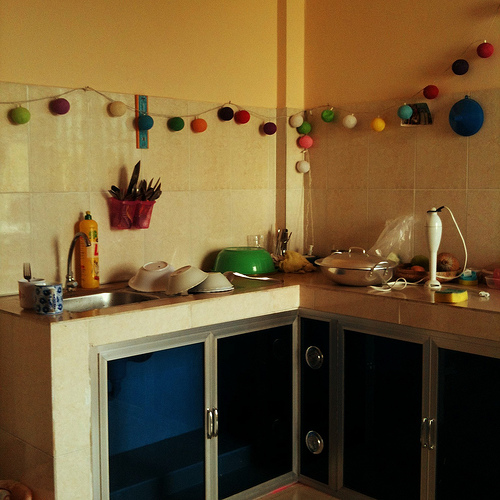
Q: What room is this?
A: It is a kitchen.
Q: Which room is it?
A: It is a kitchen.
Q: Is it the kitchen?
A: Yes, it is the kitchen.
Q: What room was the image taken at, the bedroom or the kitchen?
A: It was taken at the kitchen.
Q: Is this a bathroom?
A: No, it is a kitchen.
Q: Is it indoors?
A: Yes, it is indoors.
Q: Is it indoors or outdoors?
A: It is indoors.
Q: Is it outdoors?
A: No, it is indoors.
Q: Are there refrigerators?
A: No, there are no refrigerators.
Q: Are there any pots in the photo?
A: Yes, there is a pot.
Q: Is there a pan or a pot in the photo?
A: Yes, there is a pot.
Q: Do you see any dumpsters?
A: No, there are no dumpsters.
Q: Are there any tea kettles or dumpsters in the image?
A: No, there are no dumpsters or tea kettles.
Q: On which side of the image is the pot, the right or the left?
A: The pot is on the right of the image.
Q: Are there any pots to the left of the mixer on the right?
A: Yes, there is a pot to the left of the mixer.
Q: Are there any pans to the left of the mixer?
A: No, there is a pot to the left of the mixer.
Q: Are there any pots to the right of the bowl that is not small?
A: Yes, there is a pot to the right of the bowl.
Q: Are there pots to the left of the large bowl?
A: No, the pot is to the right of the bowl.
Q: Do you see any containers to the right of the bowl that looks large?
A: No, there is a pot to the right of the bowl.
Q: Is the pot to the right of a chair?
A: No, the pot is to the right of the bowl.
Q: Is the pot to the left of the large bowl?
A: No, the pot is to the right of the bowl.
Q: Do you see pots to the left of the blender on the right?
A: Yes, there is a pot to the left of the blender.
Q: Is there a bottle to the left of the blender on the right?
A: No, there is a pot to the left of the blender.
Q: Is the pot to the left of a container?
A: No, the pot is to the left of the blender.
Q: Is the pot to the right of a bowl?
A: Yes, the pot is to the right of a bowl.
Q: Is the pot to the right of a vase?
A: No, the pot is to the right of a bowl.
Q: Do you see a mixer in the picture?
A: Yes, there is a mixer.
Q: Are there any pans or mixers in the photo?
A: Yes, there is a mixer.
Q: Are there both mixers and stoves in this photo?
A: No, there is a mixer but no stoves.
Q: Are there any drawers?
A: No, there are no drawers.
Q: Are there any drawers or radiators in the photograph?
A: No, there are no drawers or radiators.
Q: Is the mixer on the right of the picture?
A: Yes, the mixer is on the right of the image.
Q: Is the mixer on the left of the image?
A: No, the mixer is on the right of the image.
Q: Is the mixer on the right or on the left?
A: The mixer is on the right of the image.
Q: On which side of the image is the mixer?
A: The mixer is on the right of the image.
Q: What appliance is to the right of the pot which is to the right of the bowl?
A: The appliance is a mixer.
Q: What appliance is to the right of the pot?
A: The appliance is a mixer.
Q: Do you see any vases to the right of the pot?
A: No, there is a mixer to the right of the pot.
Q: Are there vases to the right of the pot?
A: No, there is a mixer to the right of the pot.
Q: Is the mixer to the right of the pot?
A: Yes, the mixer is to the right of the pot.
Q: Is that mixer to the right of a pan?
A: No, the mixer is to the right of the pot.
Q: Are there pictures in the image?
A: No, there are no pictures.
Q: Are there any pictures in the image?
A: No, there are no pictures.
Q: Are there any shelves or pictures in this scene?
A: No, there are no pictures or shelves.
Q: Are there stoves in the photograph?
A: No, there are no stoves.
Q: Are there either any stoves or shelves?
A: No, there are no stoves or shelves.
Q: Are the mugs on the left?
A: Yes, the mugs are on the left of the image.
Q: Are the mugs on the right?
A: No, the mugs are on the left of the image.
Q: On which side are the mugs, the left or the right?
A: The mugs are on the left of the image.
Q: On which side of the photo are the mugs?
A: The mugs are on the left of the image.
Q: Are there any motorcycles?
A: No, there are no motorcycles.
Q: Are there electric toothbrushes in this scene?
A: No, there are no electric toothbrushes.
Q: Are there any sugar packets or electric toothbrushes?
A: No, there are no electric toothbrushes or sugar packets.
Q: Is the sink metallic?
A: Yes, the sink is metallic.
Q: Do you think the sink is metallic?
A: Yes, the sink is metallic.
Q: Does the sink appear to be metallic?
A: Yes, the sink is metallic.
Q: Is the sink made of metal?
A: Yes, the sink is made of metal.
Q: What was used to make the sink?
A: The sink is made of metal.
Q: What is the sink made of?
A: The sink is made of metal.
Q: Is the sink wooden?
A: No, the sink is metallic.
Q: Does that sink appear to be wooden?
A: No, the sink is metallic.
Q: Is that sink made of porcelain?
A: No, the sink is made of metal.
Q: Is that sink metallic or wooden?
A: The sink is metallic.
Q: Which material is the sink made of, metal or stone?
A: The sink is made of metal.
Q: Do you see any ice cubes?
A: No, there are no ice cubes.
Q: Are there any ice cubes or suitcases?
A: No, there are no ice cubes or suitcases.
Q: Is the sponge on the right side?
A: Yes, the sponge is on the right of the image.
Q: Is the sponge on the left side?
A: No, the sponge is on the right of the image.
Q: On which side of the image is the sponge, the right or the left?
A: The sponge is on the right of the image.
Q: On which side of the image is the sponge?
A: The sponge is on the right of the image.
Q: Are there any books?
A: No, there are no books.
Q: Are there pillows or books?
A: No, there are no books or pillows.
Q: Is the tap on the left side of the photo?
A: Yes, the tap is on the left of the image.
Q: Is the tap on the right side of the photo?
A: No, the tap is on the left of the image.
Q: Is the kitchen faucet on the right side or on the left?
A: The faucet is on the left of the image.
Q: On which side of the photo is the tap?
A: The tap is on the left of the image.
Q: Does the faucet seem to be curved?
A: Yes, the faucet is curved.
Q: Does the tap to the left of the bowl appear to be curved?
A: Yes, the faucet is curved.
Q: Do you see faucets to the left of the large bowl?
A: Yes, there is a faucet to the left of the bowl.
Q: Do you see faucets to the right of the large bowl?
A: No, the faucet is to the left of the bowl.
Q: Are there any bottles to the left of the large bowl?
A: No, there is a faucet to the left of the bowl.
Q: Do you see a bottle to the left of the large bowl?
A: No, there is a faucet to the left of the bowl.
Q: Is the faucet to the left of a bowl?
A: Yes, the faucet is to the left of a bowl.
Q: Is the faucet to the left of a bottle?
A: No, the faucet is to the left of a bowl.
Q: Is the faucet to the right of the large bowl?
A: No, the faucet is to the left of the bowl.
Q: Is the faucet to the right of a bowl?
A: No, the faucet is to the left of a bowl.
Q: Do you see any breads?
A: No, there are no breads.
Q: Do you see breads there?
A: No, there are no breads.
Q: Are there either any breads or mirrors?
A: No, there are no breads or mirrors.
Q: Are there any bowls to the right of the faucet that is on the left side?
A: Yes, there is a bowl to the right of the faucet.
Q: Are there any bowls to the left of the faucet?
A: No, the bowl is to the right of the faucet.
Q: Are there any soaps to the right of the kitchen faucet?
A: No, there is a bowl to the right of the faucet.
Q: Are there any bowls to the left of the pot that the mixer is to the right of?
A: Yes, there is a bowl to the left of the pot.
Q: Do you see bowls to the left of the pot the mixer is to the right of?
A: Yes, there is a bowl to the left of the pot.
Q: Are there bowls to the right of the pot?
A: No, the bowl is to the left of the pot.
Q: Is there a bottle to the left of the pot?
A: No, there is a bowl to the left of the pot.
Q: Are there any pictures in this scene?
A: No, there are no pictures.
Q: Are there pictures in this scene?
A: No, there are no pictures.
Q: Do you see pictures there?
A: No, there are no pictures.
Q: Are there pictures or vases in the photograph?
A: No, there are no pictures or vases.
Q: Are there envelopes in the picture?
A: No, there are no envelopes.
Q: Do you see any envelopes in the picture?
A: No, there are no envelopes.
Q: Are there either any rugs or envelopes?
A: No, there are no envelopes or rugs.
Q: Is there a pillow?
A: No, there are no pillows.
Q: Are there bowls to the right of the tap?
A: Yes, there is a bowl to the right of the tap.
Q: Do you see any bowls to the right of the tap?
A: Yes, there is a bowl to the right of the tap.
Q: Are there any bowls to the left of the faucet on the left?
A: No, the bowl is to the right of the faucet.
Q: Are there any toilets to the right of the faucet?
A: No, there is a bowl to the right of the faucet.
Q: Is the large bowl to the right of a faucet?
A: Yes, the bowl is to the right of a faucet.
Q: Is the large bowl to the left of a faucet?
A: No, the bowl is to the right of a faucet.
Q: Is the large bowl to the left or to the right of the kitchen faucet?
A: The bowl is to the right of the tap.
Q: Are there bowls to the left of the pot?
A: Yes, there is a bowl to the left of the pot.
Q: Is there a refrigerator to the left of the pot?
A: No, there is a bowl to the left of the pot.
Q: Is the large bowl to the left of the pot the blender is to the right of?
A: Yes, the bowl is to the left of the pot.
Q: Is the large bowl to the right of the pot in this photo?
A: No, the bowl is to the left of the pot.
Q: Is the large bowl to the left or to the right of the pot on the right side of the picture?
A: The bowl is to the left of the pot.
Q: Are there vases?
A: No, there are no vases.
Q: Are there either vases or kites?
A: No, there are no vases or kites.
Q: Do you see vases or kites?
A: No, there are no vases or kites.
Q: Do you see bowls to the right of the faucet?
A: Yes, there is a bowl to the right of the faucet.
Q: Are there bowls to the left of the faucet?
A: No, the bowl is to the right of the faucet.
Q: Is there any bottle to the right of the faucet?
A: No, there is a bowl to the right of the faucet.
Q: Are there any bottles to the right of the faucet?
A: No, there is a bowl to the right of the faucet.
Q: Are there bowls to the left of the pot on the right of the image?
A: Yes, there is a bowl to the left of the pot.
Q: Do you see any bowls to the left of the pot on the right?
A: Yes, there is a bowl to the left of the pot.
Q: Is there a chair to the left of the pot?
A: No, there is a bowl to the left of the pot.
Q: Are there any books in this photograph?
A: No, there are no books.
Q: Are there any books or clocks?
A: No, there are no books or clocks.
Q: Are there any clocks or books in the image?
A: No, there are no books or clocks.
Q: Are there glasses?
A: No, there are no glasses.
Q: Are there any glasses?
A: No, there are no glasses.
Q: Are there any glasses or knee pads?
A: No, there are no glasses or knee pads.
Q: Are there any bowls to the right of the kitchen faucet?
A: Yes, there is a bowl to the right of the faucet.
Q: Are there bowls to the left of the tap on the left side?
A: No, the bowl is to the right of the tap.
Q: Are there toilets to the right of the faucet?
A: No, there is a bowl to the right of the faucet.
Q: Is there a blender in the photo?
A: Yes, there is a blender.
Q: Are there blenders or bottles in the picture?
A: Yes, there is a blender.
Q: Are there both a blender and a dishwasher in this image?
A: No, there is a blender but no dishwashers.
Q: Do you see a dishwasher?
A: No, there are no dishwashers.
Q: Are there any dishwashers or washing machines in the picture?
A: No, there are no dishwashers or washing machines.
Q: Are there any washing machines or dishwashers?
A: No, there are no dishwashers or washing machines.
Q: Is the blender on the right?
A: Yes, the blender is on the right of the image.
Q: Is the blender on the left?
A: No, the blender is on the right of the image.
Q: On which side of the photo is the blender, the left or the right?
A: The blender is on the right of the image.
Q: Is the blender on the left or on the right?
A: The blender is on the right of the image.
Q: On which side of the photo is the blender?
A: The blender is on the right of the image.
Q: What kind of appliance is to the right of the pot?
A: The appliance is a blender.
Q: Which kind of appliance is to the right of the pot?
A: The appliance is a blender.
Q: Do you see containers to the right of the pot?
A: No, there is a blender to the right of the pot.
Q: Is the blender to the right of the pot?
A: Yes, the blender is to the right of the pot.